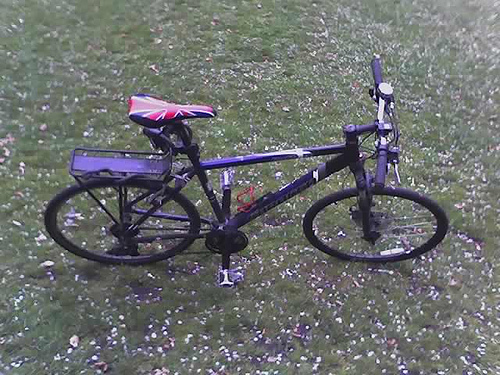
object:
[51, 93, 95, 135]
grass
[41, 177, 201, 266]
rear tire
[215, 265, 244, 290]
pedal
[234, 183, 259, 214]
holder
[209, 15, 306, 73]
grass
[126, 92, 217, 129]
alien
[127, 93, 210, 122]
union-jack design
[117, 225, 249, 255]
chain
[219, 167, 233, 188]
pedal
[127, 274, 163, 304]
dirt patch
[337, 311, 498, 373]
grass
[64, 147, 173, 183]
basket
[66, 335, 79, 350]
pebbles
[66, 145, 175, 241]
shelf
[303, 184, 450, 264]
tire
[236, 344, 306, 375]
lawn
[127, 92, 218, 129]
bike seat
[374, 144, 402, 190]
brakes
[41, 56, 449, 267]
bike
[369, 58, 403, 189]
handlebars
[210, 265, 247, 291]
debris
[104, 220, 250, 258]
bke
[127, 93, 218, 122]
flag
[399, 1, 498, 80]
ground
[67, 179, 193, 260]
spokes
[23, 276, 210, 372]
grass